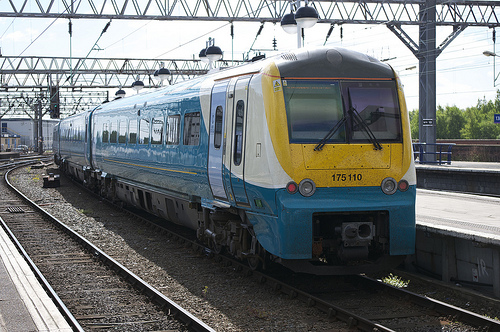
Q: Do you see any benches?
A: Yes, there is a bench.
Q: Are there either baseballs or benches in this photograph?
A: Yes, there is a bench.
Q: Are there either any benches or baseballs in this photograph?
A: Yes, there is a bench.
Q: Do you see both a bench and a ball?
A: No, there is a bench but no balls.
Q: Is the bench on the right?
A: Yes, the bench is on the right of the image.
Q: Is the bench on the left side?
A: No, the bench is on the right of the image.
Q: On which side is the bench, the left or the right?
A: The bench is on the right of the image.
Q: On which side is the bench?
A: The bench is on the right of the image.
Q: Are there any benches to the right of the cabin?
A: Yes, there is a bench to the right of the cabin.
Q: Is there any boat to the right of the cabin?
A: No, there is a bench to the right of the cabin.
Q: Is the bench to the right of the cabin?
A: Yes, the bench is to the right of the cabin.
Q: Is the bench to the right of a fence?
A: No, the bench is to the right of the cabin.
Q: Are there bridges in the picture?
A: Yes, there is a bridge.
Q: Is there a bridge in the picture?
A: Yes, there is a bridge.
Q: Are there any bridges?
A: Yes, there is a bridge.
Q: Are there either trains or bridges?
A: Yes, there is a bridge.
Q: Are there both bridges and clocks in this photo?
A: No, there is a bridge but no clocks.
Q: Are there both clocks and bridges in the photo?
A: No, there is a bridge but no clocks.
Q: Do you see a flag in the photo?
A: No, there are no flags.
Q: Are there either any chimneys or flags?
A: No, there are no flags or chimneys.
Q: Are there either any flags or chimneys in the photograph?
A: No, there are no flags or chimneys.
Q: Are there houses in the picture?
A: No, there are no houses.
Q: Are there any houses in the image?
A: No, there are no houses.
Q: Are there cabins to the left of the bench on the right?
A: Yes, there is a cabin to the left of the bench.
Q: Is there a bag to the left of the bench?
A: No, there is a cabin to the left of the bench.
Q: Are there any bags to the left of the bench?
A: No, there is a cabin to the left of the bench.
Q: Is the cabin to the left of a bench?
A: Yes, the cabin is to the left of a bench.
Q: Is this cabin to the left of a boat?
A: No, the cabin is to the left of a bench.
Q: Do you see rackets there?
A: No, there are no rackets.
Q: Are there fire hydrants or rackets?
A: No, there are no rackets or fire hydrants.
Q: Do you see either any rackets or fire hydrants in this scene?
A: No, there are no rackets or fire hydrants.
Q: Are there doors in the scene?
A: Yes, there is a door.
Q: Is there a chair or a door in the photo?
A: Yes, there is a door.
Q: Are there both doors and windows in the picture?
A: Yes, there are both a door and windows.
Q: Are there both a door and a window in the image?
A: Yes, there are both a door and a window.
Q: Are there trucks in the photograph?
A: No, there are no trucks.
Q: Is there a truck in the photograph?
A: No, there are no trucks.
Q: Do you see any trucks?
A: No, there are no trucks.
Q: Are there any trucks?
A: No, there are no trucks.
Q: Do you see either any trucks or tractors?
A: No, there are no trucks or tractors.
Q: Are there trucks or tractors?
A: No, there are no trucks or tractors.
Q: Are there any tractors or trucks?
A: No, there are no trucks or tractors.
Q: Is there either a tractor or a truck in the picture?
A: No, there are no trucks or tractors.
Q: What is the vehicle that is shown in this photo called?
A: The vehicle is a locomotive.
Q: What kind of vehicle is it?
A: The vehicle is a locomotive.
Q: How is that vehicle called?
A: This is a locomotive.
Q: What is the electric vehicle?
A: The vehicle is a locomotive.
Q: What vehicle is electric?
A: The vehicle is a locomotive.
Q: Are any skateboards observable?
A: No, there are no skateboards.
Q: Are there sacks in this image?
A: No, there are no sacks.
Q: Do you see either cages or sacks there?
A: No, there are no sacks or cages.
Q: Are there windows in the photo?
A: Yes, there are windows.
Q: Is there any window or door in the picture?
A: Yes, there are windows.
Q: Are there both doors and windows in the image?
A: Yes, there are both windows and a door.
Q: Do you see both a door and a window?
A: Yes, there are both a window and a door.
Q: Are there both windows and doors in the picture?
A: Yes, there are both windows and a door.